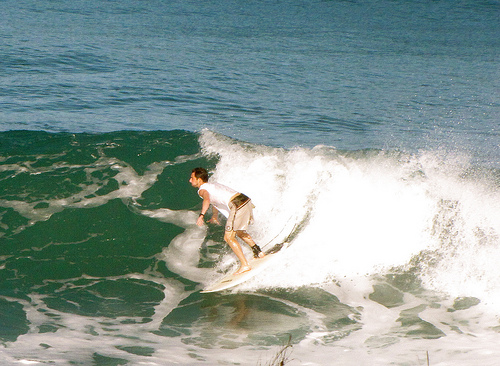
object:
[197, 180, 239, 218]
shirt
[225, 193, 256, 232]
white shorts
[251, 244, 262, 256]
black cable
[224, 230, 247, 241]
knees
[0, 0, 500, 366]
sea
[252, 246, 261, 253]
ankle wrap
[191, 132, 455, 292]
wake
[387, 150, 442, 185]
ground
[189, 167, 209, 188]
head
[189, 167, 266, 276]
man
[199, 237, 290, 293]
board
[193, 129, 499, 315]
waves